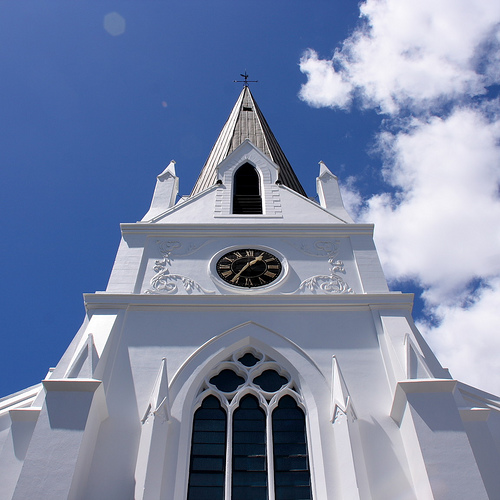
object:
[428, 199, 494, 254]
clouds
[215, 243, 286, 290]
clock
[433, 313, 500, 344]
clouds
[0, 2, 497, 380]
sky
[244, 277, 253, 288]
numeral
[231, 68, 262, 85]
vane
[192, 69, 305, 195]
roof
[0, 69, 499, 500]
building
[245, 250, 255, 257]
number twelve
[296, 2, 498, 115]
clouds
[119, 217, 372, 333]
wall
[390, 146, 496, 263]
white clouds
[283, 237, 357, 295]
design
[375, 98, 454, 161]
clouds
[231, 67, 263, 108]
top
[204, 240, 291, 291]
time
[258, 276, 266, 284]
five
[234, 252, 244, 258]
numeral